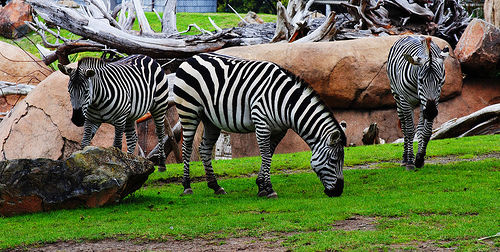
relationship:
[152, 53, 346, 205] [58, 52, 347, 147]
animal has stripe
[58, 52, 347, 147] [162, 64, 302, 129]
stripe on animal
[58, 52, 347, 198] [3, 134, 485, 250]
animal on grass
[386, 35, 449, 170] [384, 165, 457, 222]
animal on grass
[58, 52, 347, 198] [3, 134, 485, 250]
animal looking down at grass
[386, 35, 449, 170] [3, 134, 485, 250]
animal looking down at grass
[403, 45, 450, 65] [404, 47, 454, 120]
ears on h head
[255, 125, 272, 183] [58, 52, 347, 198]
leg on animal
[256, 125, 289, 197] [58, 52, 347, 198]
leg on animal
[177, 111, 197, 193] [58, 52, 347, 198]
leg on animal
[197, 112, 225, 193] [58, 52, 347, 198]
leg on animal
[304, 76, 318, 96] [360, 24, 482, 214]
mane on zebra.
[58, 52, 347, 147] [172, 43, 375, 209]
stripe on animal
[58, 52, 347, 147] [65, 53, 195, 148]
stripe on animal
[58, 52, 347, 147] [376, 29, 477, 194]
stripe on animal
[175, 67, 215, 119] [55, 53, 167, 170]
stripe on animal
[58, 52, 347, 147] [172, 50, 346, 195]
stripe on animal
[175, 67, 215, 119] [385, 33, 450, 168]
stripe on animal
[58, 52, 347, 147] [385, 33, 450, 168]
stripe on animal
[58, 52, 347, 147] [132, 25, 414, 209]
stripe on animal